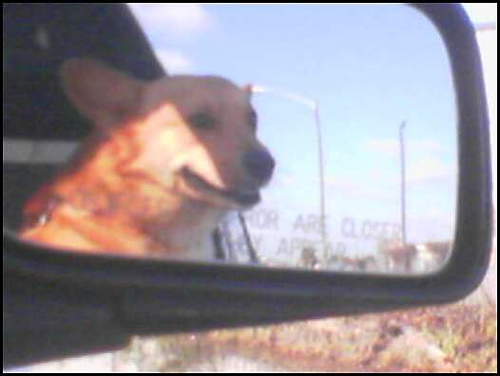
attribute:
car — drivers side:
[6, 21, 484, 357]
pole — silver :
[308, 101, 420, 262]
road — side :
[234, 350, 426, 372]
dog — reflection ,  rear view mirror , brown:
[13, 53, 277, 264]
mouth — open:
[177, 163, 271, 213]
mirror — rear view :
[0, 3, 494, 329]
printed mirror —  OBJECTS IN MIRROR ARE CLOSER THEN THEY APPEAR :
[21, 175, 408, 274]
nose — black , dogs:
[234, 143, 286, 182]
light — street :
[387, 111, 416, 248]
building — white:
[342, 236, 456, 278]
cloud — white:
[128, 1, 206, 74]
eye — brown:
[182, 108, 222, 138]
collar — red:
[21, 183, 118, 244]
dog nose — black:
[238, 149, 283, 184]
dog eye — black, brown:
[180, 109, 229, 140]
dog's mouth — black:
[167, 160, 266, 213]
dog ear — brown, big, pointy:
[48, 45, 146, 131]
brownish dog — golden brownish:
[29, 53, 285, 259]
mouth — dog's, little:
[176, 162, 262, 211]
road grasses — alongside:
[166, 304, 499, 374]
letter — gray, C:
[337, 213, 349, 234]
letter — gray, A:
[293, 207, 305, 234]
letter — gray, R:
[394, 217, 405, 245]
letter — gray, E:
[383, 221, 398, 244]